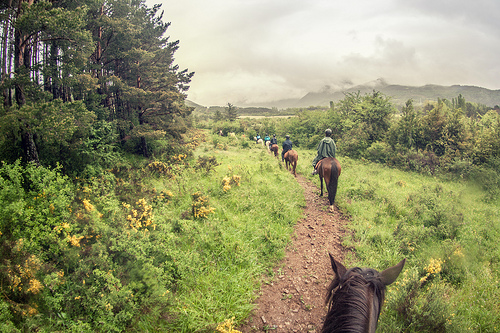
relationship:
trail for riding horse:
[293, 207, 326, 322] [314, 155, 339, 205]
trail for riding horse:
[293, 207, 326, 322] [319, 251, 404, 331]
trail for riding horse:
[293, 207, 326, 322] [284, 147, 298, 174]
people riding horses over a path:
[253, 123, 355, 205] [256, 124, 346, 309]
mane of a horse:
[336, 277, 360, 332] [311, 247, 407, 332]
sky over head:
[145, 1, 497, 108] [324, 129, 333, 138]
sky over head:
[145, 1, 497, 108] [283, 134, 290, 141]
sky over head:
[145, 1, 497, 108] [271, 134, 276, 139]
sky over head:
[145, 1, 497, 108] [263, 133, 268, 137]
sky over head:
[145, 1, 497, 108] [254, 133, 259, 137]